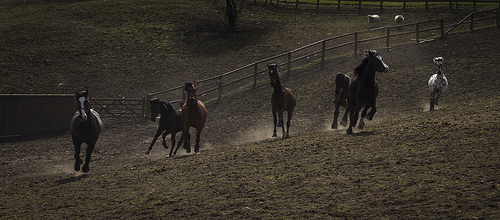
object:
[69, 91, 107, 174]
horse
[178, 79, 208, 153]
horse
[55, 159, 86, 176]
dust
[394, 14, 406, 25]
sheep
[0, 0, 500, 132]
fence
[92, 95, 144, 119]
door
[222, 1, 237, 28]
tree trunk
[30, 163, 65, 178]
dirt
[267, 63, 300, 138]
horse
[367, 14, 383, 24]
sheep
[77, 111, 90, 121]
nose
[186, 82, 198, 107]
head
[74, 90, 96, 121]
head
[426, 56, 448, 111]
horse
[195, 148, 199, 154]
hoof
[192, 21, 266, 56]
shadow